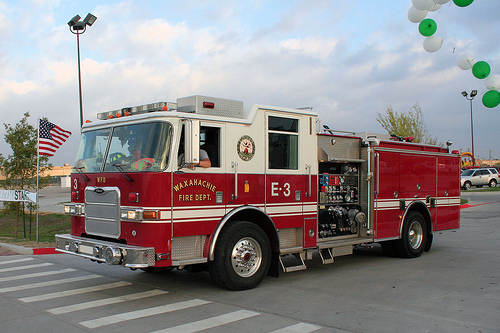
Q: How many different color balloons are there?
A: 2.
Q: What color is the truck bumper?
A: Silver.